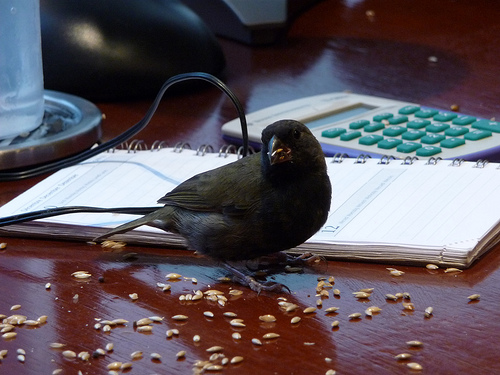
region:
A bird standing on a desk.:
[70, 115, 355, 305]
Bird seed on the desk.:
[31, 292, 426, 372]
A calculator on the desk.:
[215, 60, 495, 156]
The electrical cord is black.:
[0, 55, 250, 176]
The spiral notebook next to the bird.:
[1, 120, 497, 267]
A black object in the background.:
[31, 0, 217, 96]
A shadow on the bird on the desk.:
[95, 270, 386, 372]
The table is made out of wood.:
[345, 326, 390, 367]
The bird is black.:
[83, 111, 341, 302]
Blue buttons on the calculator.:
[318, 102, 498, 155]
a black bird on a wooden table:
[96, 117, 332, 290]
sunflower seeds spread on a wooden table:
[2, 295, 439, 374]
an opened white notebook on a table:
[0, 142, 498, 263]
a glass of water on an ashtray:
[3, 0, 45, 137]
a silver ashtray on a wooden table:
[0, 88, 104, 178]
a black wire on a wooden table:
[0, 69, 255, 224]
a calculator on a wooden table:
[225, 88, 499, 167]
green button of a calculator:
[321, 104, 498, 156]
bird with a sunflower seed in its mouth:
[259, 118, 324, 170]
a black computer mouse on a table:
[46, 0, 231, 106]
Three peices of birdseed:
[392, 340, 422, 368]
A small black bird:
[94, 120, 331, 295]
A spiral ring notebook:
[0, 140, 499, 270]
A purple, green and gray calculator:
[220, 91, 498, 161]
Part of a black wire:
[0, 69, 252, 227]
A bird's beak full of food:
[264, 136, 291, 168]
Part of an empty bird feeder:
[1, 1, 106, 171]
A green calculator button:
[355, 131, 383, 146]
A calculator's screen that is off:
[297, 101, 379, 128]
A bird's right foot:
[214, 259, 291, 298]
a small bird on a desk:
[80, 116, 333, 290]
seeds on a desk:
[0, 231, 480, 371]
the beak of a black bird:
[265, 135, 286, 167]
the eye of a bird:
[292, 126, 300, 139]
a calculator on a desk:
[220, 90, 498, 160]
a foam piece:
[39, 2, 225, 91]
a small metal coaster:
[0, 92, 105, 169]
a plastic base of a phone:
[200, 0, 290, 40]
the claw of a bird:
[230, 267, 294, 298]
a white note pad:
[6, 143, 498, 261]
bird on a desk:
[44, 71, 403, 306]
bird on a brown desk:
[87, 45, 360, 292]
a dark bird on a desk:
[61, 68, 447, 329]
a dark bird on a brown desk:
[62, 100, 371, 314]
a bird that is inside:
[55, 69, 420, 340]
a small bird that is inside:
[50, 81, 325, 374]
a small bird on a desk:
[52, 55, 422, 330]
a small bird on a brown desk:
[58, 77, 433, 354]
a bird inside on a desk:
[39, 43, 474, 374]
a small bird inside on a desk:
[47, 54, 479, 369]